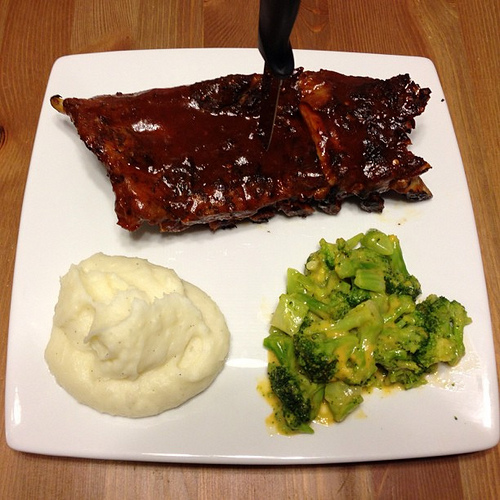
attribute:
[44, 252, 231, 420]
mashed potatoes — piled, soft, vegetable, creamy, white, whipped, buttery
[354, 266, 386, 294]
broccoli — cheesy, green, vegetable, chopped, stalk, dark green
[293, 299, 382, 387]
broccoli — cheesy, green, vegetable, chopped, floret, dark green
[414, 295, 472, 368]
broccoli — cheesy, green, vegetable, chopped, floret, dark green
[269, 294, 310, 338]
broccoli — cheesy, green, vegetable, chopped, stalk, dark green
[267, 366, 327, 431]
broccoli — cheesy, green, vegetable, chopped, floret, dark green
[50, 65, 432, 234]
ribs — bbq'd, meat, saucy, barbecued, bbq, half rack, brown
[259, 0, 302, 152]
knife — sharp, black, silver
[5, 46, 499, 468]
plate — white, square, oblong, bright, full, porcelain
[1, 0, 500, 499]
table — wood, light brown, wooden, brown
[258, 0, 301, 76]
handle — black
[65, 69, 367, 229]
sauce — shiny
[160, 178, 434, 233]
bones — large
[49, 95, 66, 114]
bone — large, white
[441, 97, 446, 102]
speck — black